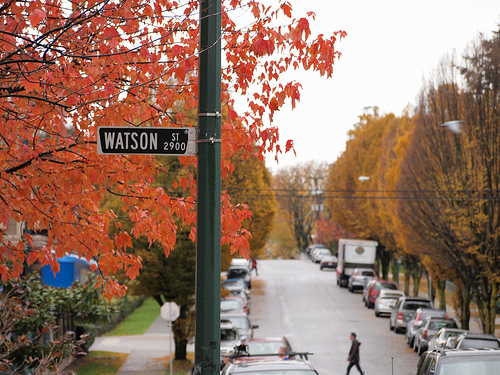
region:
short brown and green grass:
[122, 307, 139, 323]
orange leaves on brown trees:
[18, 33, 57, 75]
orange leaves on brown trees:
[32, 42, 73, 100]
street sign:
[98, 123, 187, 176]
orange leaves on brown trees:
[347, 146, 397, 172]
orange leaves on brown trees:
[418, 144, 439, 170]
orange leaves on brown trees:
[406, 199, 443, 220]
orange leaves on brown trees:
[72, 160, 129, 215]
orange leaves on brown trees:
[127, 199, 187, 229]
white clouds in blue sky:
[370, 23, 416, 67]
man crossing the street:
[324, 320, 380, 374]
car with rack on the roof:
[222, 348, 333, 373]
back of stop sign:
[159, 296, 181, 373]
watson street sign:
[85, 113, 242, 165]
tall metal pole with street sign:
[171, 1, 285, 373]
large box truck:
[319, 237, 389, 293]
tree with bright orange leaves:
[1, 6, 339, 324]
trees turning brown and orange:
[323, 101, 490, 312]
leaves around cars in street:
[217, 263, 283, 306]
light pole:
[339, 168, 391, 243]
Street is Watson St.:
[92, 122, 202, 157]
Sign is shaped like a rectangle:
[95, 122, 200, 159]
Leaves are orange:
[0, 1, 354, 303]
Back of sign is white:
[157, 298, 182, 323]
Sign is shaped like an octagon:
[158, 300, 184, 324]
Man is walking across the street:
[339, 330, 369, 374]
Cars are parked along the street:
[220, 235, 499, 373]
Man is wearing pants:
[343, 360, 364, 374]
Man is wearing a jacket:
[345, 337, 363, 363]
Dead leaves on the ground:
[82, 343, 227, 365]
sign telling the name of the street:
[99, 123, 199, 158]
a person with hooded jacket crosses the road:
[333, 315, 369, 372]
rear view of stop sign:
[153, 301, 183, 369]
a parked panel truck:
[333, 225, 381, 298]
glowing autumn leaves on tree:
[1, 2, 365, 288]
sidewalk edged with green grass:
[93, 294, 181, 373]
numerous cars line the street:
[209, 238, 458, 373]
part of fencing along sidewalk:
[0, 290, 85, 370]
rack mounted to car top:
[217, 344, 319, 366]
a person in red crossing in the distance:
[246, 253, 262, 280]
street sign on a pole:
[94, 124, 199, 155]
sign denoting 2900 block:
[93, 127, 193, 156]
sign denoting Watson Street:
[97, 125, 198, 156]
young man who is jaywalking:
[345, 333, 363, 373]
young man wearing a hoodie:
[343, 332, 363, 373]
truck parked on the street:
[334, 235, 377, 287]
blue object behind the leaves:
[42, 250, 99, 289]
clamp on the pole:
[195, 136, 220, 145]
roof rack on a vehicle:
[227, 350, 315, 364]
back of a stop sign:
[162, 301, 179, 373]